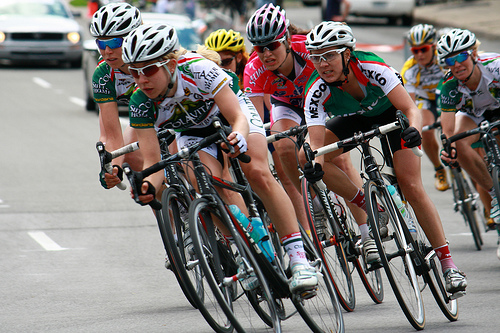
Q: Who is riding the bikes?
A: Racers.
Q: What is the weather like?
A: Sunny.